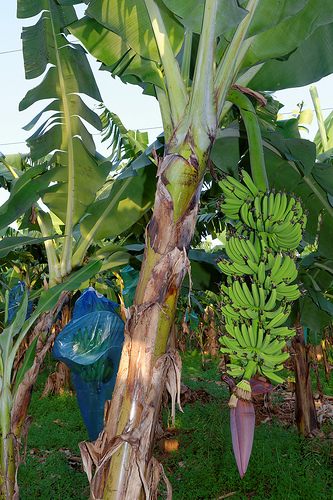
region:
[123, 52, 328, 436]
bananas hanging from a tree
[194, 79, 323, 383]
bananas hanging from a bench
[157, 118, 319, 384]
bananas ready to be picked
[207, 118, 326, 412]
green bananas that are outside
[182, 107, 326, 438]
green banana hanging on tree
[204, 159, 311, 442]
green banana hanging on branch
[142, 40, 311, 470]
a banana branch hanging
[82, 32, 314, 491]
a banana tree branch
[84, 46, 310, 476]
a tree is outside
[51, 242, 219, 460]
a bag over the bananas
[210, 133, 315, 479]
branch with lots of green bananas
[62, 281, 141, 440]
bananas covered in blue plastic bag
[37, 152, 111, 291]
large banana leaf tree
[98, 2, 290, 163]
large leaves sticking up on a tree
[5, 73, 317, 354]
jungle with banana trees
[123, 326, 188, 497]
dried leaves peeling of a tree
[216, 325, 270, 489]
purple colored end tip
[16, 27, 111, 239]
large tropical tree leaf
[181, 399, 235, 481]
green bushing in the grown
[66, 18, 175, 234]
sunlight coming in through the branches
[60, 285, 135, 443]
big blue flowers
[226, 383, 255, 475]
purple bud of flower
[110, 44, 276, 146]
top of middle tree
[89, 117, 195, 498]
trunk of middle tree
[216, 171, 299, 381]
bananas growing off the tree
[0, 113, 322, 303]
tops of the other trees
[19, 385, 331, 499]
green foliage on the ground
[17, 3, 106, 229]
long leaf on the left side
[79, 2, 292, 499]
middle tree with bananas growing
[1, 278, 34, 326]
small blue flower on the left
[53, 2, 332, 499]
THIS IS A BANANA TREE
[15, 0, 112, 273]
THIS IS A BANANA LEAF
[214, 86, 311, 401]
THE BANANAS ARE ON A STALK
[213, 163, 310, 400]
THIS IS A BUNCH OF BANANAS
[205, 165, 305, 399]
THE BUNCH OF BANANAS IS LARGE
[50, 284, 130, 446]
THE BANANAS ARE IN PLASTIC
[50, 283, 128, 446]
THE PLASTIC IS BLUE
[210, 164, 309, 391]
THE BANANAS ARE ON THE TREE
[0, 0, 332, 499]
THE TREES ARE TALL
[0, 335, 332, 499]
THE GRASS AND DRIED LEAVES COVER THE GROUND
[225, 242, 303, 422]
banana bunches hanging from their tree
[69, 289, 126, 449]
blue plastic covering hanging bananas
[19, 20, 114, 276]
large green banana tree leaves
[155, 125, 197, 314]
the peeling trunk of a banana tree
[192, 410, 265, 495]
green shrubbery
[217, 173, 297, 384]
a whole bunch of bunches of bananas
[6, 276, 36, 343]
another bunch of bananas covered by blue plastic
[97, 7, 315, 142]
the top of a banana tree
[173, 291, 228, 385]
a thick grouping of trees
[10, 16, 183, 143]
a bright daytime sky